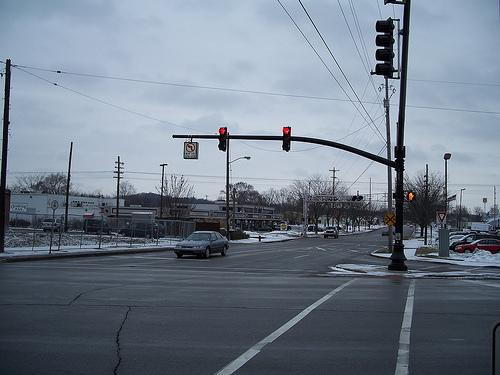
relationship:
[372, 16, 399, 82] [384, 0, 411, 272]
lights on a pole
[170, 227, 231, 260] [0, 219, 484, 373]
car on road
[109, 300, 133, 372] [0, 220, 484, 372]
crack in pavement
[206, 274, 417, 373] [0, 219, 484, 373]
paint on road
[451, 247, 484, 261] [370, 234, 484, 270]
snow on curb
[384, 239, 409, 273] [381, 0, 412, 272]
base of a pole